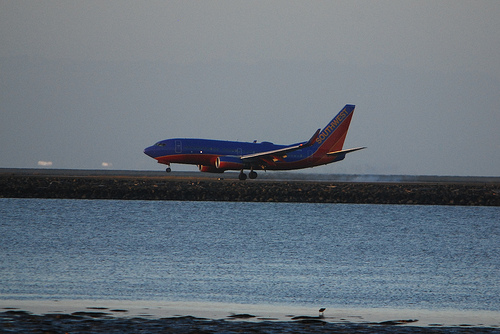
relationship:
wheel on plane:
[237, 172, 248, 185] [147, 97, 364, 187]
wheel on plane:
[245, 166, 265, 183] [147, 97, 364, 187]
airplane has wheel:
[124, 95, 362, 205] [237, 165, 257, 183]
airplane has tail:
[142, 104, 368, 182] [306, 103, 356, 153]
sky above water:
[0, 0, 477, 101] [0, 195, 499, 324]